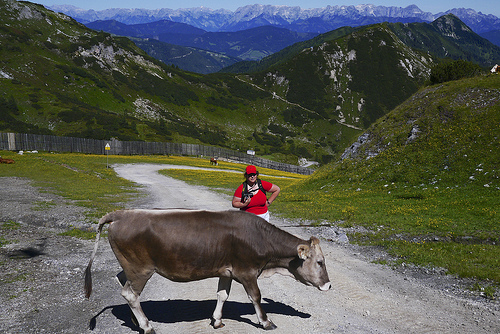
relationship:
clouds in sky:
[278, 8, 310, 36] [33, 1, 498, 18]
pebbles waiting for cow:
[382, 301, 419, 326] [84, 207, 335, 332]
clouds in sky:
[41, 0, 500, 14] [38, 0, 497, 10]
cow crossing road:
[84, 207, 335, 332] [109, 160, 496, 331]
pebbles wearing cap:
[382, 301, 419, 326] [243, 162, 259, 173]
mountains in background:
[49, 2, 499, 72] [8, 5, 484, 156]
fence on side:
[16, 127, 223, 224] [8, 0, 325, 146]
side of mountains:
[8, 0, 325, 146] [36, 4, 315, 150]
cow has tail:
[84, 207, 335, 332] [71, 211, 114, 294]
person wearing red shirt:
[224, 157, 279, 224] [231, 182, 278, 216]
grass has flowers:
[372, 150, 476, 248] [375, 174, 407, 208]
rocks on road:
[47, 245, 63, 318] [129, 165, 207, 203]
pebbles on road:
[382, 301, 419, 326] [129, 165, 207, 203]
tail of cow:
[83, 209, 113, 297] [84, 207, 335, 332]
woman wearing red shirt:
[233, 167, 280, 223] [233, 178, 271, 212]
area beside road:
[0, 143, 133, 241] [109, 160, 496, 331]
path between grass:
[104, 149, 498, 331] [21, 137, 494, 267]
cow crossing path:
[84, 207, 335, 332] [104, 149, 498, 331]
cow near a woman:
[84, 207, 335, 332] [233, 161, 281, 223]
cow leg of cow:
[224, 259, 281, 331] [84, 207, 335, 332]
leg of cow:
[209, 275, 247, 332] [74, 200, 389, 332]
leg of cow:
[118, 275, 161, 324] [72, 211, 364, 329]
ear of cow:
[294, 242, 314, 262] [84, 207, 335, 332]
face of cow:
[296, 235, 339, 290] [84, 207, 335, 332]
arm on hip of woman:
[262, 183, 285, 210] [224, 161, 276, 230]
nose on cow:
[325, 282, 332, 291] [84, 207, 335, 332]